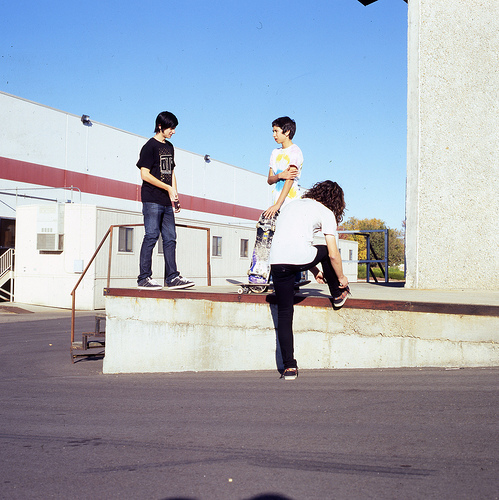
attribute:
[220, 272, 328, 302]
skateboard — black, white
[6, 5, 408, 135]
sky — blue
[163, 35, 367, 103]
sky — clear, blue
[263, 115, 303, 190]
boy — one